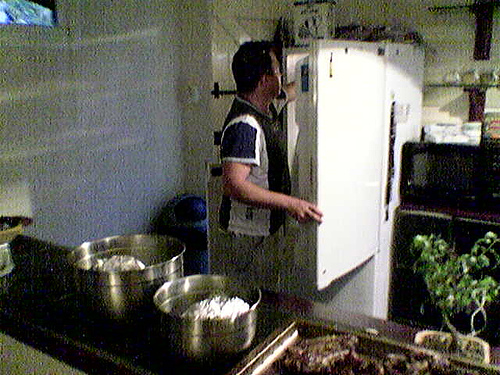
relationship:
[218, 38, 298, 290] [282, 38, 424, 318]
man looking in refrigerator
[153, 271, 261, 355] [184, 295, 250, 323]
pot full of rice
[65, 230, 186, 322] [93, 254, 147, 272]
pot full of noodles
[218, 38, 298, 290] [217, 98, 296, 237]
man wearing shirt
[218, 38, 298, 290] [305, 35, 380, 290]
man holding refrigerator door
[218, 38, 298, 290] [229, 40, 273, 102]
man has hair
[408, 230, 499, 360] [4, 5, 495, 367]
plant in kitchen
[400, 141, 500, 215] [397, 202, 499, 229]
microwave oven on counter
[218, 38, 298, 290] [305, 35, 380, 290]
man opening refrigerator door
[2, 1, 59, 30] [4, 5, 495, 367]
window in kitchen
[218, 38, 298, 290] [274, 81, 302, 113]
man has arm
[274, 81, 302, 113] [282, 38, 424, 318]
arm in refrigerator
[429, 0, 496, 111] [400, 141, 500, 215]
shelf above microwave oven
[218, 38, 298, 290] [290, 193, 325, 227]
man has hand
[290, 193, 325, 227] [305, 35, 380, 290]
hand on refrigerator door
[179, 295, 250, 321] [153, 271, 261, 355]
rice in pot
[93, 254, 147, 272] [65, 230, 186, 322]
noodles in pot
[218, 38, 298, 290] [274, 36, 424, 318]
man in fridge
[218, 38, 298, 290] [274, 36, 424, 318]
man reaching into fridge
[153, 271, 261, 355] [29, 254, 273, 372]
pot cooking on stove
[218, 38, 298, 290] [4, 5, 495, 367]
man in kitchen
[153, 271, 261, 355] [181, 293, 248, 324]
pot with noodles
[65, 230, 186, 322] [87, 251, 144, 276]
pot with noodles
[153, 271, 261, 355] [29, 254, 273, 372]
pot on stove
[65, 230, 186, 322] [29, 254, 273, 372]
pot on stove